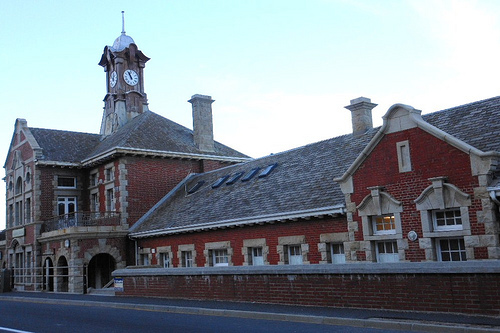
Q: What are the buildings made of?
A: Red brick.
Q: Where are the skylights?
A: Building on the right.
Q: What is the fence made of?
A: Brick.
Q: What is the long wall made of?
A: Brick.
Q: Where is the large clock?
A: On the tower.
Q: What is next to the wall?
A: The sidewalk.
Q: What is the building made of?
A: Brick.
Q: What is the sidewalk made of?
A: Concrete.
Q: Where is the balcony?
A: On the taller building.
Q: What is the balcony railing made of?
A: Metal.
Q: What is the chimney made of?
A: Brick.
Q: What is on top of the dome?
A: A pole.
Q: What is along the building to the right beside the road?
A: A brick wall.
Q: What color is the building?
A: Red.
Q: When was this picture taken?
A: Daytime.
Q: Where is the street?
A: On the left.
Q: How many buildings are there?
A: One.